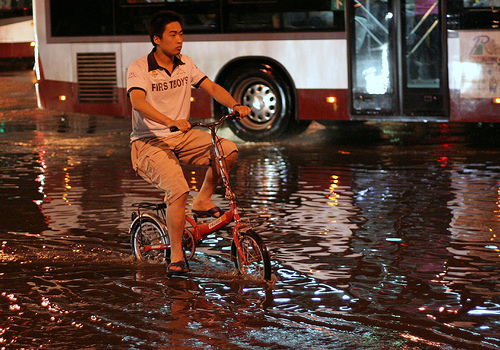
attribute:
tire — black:
[223, 67, 295, 151]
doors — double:
[338, 0, 453, 126]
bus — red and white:
[29, 0, 498, 142]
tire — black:
[126, 216, 186, 269]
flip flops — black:
[151, 190, 231, 273]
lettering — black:
[142, 74, 191, 91]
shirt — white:
[132, 49, 204, 139]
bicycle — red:
[125, 109, 271, 283]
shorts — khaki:
[130, 127, 238, 207]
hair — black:
[149, 18, 180, 45]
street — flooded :
[64, 236, 324, 327]